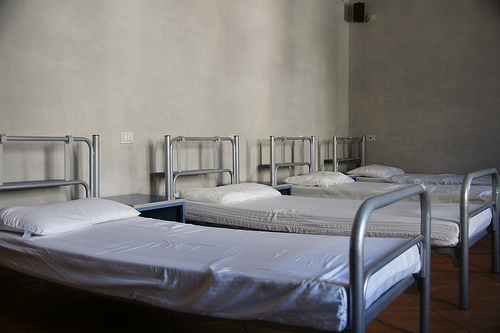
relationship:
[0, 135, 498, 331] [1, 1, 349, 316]
beds against wall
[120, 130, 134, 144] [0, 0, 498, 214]
light switch on wall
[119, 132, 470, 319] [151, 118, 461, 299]
beds with mattresses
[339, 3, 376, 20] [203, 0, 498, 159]
equipment piece attached to wall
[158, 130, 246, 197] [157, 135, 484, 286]
board on bed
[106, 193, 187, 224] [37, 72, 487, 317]
table between beds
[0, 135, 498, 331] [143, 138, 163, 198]
beds made shadows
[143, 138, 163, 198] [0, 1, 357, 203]
shadows are on wall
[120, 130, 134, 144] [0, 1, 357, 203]
light switch are on wall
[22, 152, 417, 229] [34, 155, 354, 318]
pillow on bed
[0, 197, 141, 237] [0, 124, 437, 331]
pillow on bed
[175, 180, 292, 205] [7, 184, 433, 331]
pillow on bed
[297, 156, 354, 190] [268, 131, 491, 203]
pillow on bed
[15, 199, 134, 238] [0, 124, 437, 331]
pillow on bed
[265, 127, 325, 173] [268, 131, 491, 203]
head board on bed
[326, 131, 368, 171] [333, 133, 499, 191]
head board on bed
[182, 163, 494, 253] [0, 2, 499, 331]
bed in room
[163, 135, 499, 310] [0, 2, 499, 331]
bed in room